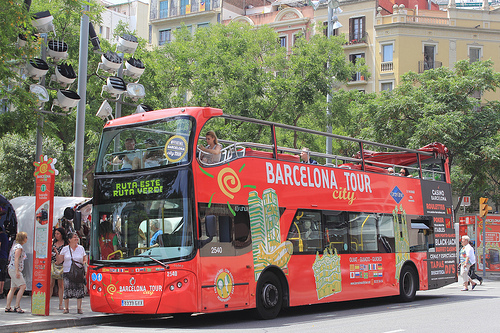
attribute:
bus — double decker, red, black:
[84, 103, 462, 330]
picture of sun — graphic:
[194, 149, 263, 221]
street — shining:
[14, 274, 498, 333]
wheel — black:
[249, 264, 291, 322]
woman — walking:
[454, 233, 486, 294]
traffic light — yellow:
[474, 190, 493, 284]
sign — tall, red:
[29, 149, 54, 315]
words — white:
[263, 150, 378, 203]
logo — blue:
[388, 184, 408, 205]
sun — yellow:
[212, 158, 245, 200]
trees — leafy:
[1, 6, 499, 136]